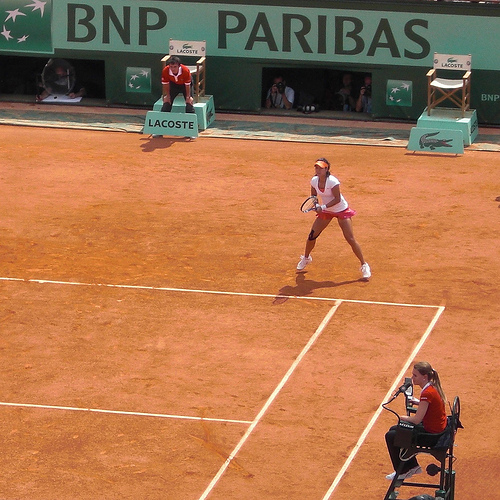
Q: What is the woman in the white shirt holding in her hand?
A: A tennis racket.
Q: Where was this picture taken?
A: A tennis court.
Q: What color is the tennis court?
A: Red.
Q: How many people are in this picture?
A: 3.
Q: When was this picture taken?
A: Daytime.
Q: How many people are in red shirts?
A: 2.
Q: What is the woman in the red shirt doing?
A: Sitting.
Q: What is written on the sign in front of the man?
A: LACOSTE.